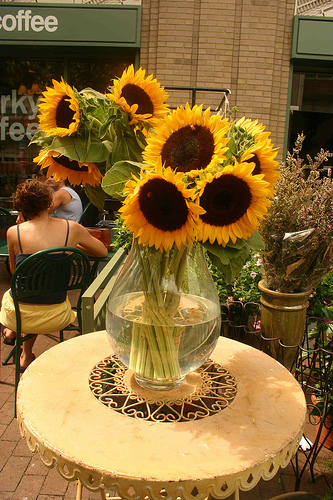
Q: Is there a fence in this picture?
A: No, there are no fences.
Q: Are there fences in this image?
A: No, there are no fences.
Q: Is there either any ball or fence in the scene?
A: No, there are no fences or balls.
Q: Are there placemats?
A: No, there are no placemats.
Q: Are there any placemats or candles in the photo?
A: No, there are no placemats or candles.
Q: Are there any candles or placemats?
A: No, there are no placemats or candles.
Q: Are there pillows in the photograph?
A: No, there are no pillows.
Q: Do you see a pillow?
A: No, there are no pillows.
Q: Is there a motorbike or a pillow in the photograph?
A: No, there are no pillows or motorcycles.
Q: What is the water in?
A: The water is in the vase.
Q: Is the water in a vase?
A: Yes, the water is in a vase.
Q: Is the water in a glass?
A: No, the water is in a vase.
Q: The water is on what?
A: The water is on the table.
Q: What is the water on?
A: The water is on the table.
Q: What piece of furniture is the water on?
A: The water is on the table.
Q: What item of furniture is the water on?
A: The water is on the table.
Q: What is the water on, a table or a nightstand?
A: The water is on a table.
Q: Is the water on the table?
A: Yes, the water is on the table.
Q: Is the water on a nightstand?
A: No, the water is on the table.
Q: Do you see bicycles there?
A: No, there are no bicycles.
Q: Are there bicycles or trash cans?
A: No, there are no bicycles or trash cans.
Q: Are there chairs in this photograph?
A: Yes, there is a chair.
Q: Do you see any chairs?
A: Yes, there is a chair.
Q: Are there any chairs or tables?
A: Yes, there is a chair.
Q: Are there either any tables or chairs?
A: Yes, there is a chair.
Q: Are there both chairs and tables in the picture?
A: Yes, there are both a chair and a table.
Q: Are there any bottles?
A: No, there are no bottles.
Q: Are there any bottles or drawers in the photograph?
A: No, there are no bottles or drawers.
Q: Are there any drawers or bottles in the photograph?
A: No, there are no bottles or drawers.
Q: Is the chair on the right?
A: No, the chair is on the left of the image.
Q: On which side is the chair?
A: The chair is on the left of the image.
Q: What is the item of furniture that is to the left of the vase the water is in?
A: The piece of furniture is a chair.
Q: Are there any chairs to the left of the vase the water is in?
A: Yes, there is a chair to the left of the vase.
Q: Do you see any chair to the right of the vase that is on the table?
A: No, the chair is to the left of the vase.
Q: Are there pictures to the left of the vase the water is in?
A: No, there is a chair to the left of the vase.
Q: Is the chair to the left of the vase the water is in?
A: Yes, the chair is to the left of the vase.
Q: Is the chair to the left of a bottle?
A: No, the chair is to the left of the vase.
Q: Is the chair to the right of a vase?
A: No, the chair is to the left of a vase.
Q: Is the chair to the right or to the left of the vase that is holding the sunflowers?
A: The chair is to the left of the vase.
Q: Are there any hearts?
A: Yes, there is a heart.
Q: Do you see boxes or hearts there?
A: Yes, there is a heart.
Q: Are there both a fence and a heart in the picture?
A: No, there is a heart but no fences.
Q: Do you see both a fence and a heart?
A: No, there is a heart but no fences.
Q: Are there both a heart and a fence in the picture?
A: No, there is a heart but no fences.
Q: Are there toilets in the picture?
A: No, there are no toilets.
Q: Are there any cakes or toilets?
A: No, there are no toilets or cakes.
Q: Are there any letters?
A: Yes, there are letters.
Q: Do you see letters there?
A: Yes, there are letters.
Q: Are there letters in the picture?
A: Yes, there are letters.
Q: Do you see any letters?
A: Yes, there are letters.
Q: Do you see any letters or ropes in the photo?
A: Yes, there are letters.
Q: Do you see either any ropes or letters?
A: Yes, there are letters.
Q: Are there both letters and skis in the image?
A: No, there are letters but no skis.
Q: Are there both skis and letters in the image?
A: No, there are letters but no skis.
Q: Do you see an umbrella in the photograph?
A: No, there are no umbrellas.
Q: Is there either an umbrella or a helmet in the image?
A: No, there are no umbrellas or helmets.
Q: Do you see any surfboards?
A: No, there are no surfboards.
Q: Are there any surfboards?
A: No, there are no surfboards.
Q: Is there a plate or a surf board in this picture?
A: No, there are no surfboards or plates.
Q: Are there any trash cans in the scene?
A: No, there are no trash cans.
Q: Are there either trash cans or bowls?
A: No, there are no trash cans or bowls.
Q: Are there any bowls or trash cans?
A: No, there are no trash cans or bowls.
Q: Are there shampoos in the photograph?
A: No, there are no shampoos.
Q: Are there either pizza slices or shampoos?
A: No, there are no shampoos or pizza slices.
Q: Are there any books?
A: No, there are no books.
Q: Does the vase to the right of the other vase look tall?
A: Yes, the vase is tall.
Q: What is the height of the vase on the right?
A: The vase is tall.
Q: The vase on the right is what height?
A: The vase is tall.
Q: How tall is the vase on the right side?
A: The vase is tall.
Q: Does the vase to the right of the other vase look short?
A: No, the vase is tall.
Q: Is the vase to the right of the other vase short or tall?
A: The vase is tall.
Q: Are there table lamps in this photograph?
A: No, there are no table lamps.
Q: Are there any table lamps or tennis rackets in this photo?
A: No, there are no table lamps or tennis rackets.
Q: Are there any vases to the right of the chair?
A: Yes, there is a vase to the right of the chair.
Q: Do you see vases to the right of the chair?
A: Yes, there is a vase to the right of the chair.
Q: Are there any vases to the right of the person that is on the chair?
A: Yes, there is a vase to the right of the person.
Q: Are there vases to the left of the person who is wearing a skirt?
A: No, the vase is to the right of the person.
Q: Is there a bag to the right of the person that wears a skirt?
A: No, there is a vase to the right of the person.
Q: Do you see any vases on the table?
A: Yes, there is a vase on the table.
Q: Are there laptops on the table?
A: No, there is a vase on the table.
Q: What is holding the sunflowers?
A: The vase is holding the sunflowers.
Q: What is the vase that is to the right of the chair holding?
A: The vase is holding the sunflowers.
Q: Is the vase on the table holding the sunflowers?
A: Yes, the vase is holding the sunflowers.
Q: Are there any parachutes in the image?
A: No, there are no parachutes.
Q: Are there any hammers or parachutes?
A: No, there are no parachutes or hammers.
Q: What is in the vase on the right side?
A: The flower is in the vase.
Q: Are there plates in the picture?
A: No, there are no plates.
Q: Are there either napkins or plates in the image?
A: No, there are no plates or napkins.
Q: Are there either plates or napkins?
A: No, there are no plates or napkins.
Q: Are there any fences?
A: No, there are no fences.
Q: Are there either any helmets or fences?
A: No, there are no fences or helmets.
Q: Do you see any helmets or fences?
A: No, there are no fences or helmets.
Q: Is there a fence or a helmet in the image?
A: No, there are no fences or helmets.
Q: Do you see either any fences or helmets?
A: No, there are no fences or helmets.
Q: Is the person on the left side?
A: Yes, the person is on the left of the image.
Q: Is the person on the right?
A: No, the person is on the left of the image.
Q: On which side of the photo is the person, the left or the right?
A: The person is on the left of the image.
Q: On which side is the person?
A: The person is on the left of the image.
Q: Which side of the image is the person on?
A: The person is on the left of the image.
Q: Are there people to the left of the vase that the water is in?
A: Yes, there is a person to the left of the vase.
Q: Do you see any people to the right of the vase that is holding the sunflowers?
A: No, the person is to the left of the vase.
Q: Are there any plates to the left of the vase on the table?
A: No, there is a person to the left of the vase.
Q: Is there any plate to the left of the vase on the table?
A: No, there is a person to the left of the vase.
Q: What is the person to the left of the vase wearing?
A: The person is wearing a skirt.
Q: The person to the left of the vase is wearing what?
A: The person is wearing a skirt.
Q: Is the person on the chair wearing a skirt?
A: Yes, the person is wearing a skirt.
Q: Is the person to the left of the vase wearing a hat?
A: No, the person is wearing a skirt.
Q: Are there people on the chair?
A: Yes, there is a person on the chair.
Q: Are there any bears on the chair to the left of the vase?
A: No, there is a person on the chair.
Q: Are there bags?
A: No, there are no bags.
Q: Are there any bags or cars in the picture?
A: No, there are no bags or cars.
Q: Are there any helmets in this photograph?
A: No, there are no helmets.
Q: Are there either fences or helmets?
A: No, there are no helmets or fences.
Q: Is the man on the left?
A: Yes, the man is on the left of the image.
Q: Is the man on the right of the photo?
A: No, the man is on the left of the image.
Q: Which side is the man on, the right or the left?
A: The man is on the left of the image.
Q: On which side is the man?
A: The man is on the left of the image.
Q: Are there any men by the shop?
A: Yes, there is a man by the shop.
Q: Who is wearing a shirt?
A: The man is wearing a shirt.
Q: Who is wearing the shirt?
A: The man is wearing a shirt.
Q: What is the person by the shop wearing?
A: The man is wearing a shirt.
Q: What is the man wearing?
A: The man is wearing a shirt.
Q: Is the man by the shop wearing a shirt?
A: Yes, the man is wearing a shirt.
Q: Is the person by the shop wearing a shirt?
A: Yes, the man is wearing a shirt.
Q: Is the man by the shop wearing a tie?
A: No, the man is wearing a shirt.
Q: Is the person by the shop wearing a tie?
A: No, the man is wearing a shirt.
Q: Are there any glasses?
A: No, there are no glasses.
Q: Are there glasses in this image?
A: No, there are no glasses.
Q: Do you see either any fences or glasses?
A: No, there are no glasses or fences.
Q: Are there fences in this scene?
A: No, there are no fences.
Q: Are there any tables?
A: Yes, there is a table.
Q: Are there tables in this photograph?
A: Yes, there is a table.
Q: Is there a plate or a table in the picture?
A: Yes, there is a table.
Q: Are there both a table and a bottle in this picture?
A: No, there is a table but no bottles.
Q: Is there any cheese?
A: No, there is no cheese.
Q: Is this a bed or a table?
A: This is a table.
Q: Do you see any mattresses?
A: No, there are no mattresses.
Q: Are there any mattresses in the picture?
A: No, there are no mattresses.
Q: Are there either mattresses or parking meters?
A: No, there are no mattresses or parking meters.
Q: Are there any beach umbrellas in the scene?
A: No, there are no beach umbrellas.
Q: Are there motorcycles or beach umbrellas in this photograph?
A: No, there are no beach umbrellas or motorcycles.